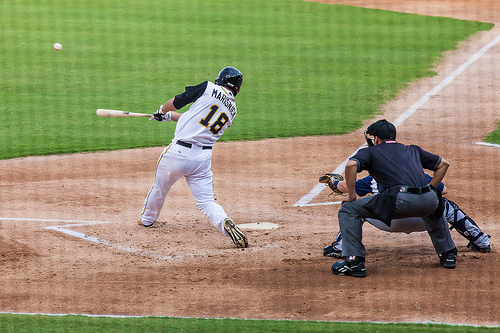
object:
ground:
[0, 0, 500, 333]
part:
[95, 109, 108, 117]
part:
[378, 126, 388, 135]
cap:
[366, 119, 397, 141]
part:
[223, 75, 233, 82]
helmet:
[215, 66, 243, 92]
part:
[190, 106, 204, 119]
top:
[171, 80, 238, 148]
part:
[302, 187, 320, 201]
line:
[0, 217, 103, 221]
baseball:
[53, 43, 63, 51]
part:
[56, 45, 60, 48]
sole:
[223, 219, 248, 248]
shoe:
[224, 218, 249, 248]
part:
[302, 139, 329, 163]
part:
[205, 204, 225, 219]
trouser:
[138, 137, 231, 237]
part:
[123, 18, 163, 46]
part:
[129, 113, 139, 118]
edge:
[0, 310, 499, 333]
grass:
[0, 312, 500, 333]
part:
[177, 139, 192, 148]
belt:
[176, 140, 213, 151]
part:
[336, 264, 356, 273]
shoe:
[332, 261, 367, 278]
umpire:
[330, 119, 458, 278]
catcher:
[319, 167, 494, 257]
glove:
[318, 173, 345, 197]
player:
[136, 66, 248, 248]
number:
[198, 104, 230, 135]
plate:
[237, 221, 279, 229]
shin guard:
[446, 198, 491, 248]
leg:
[445, 200, 495, 252]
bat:
[95, 108, 152, 117]